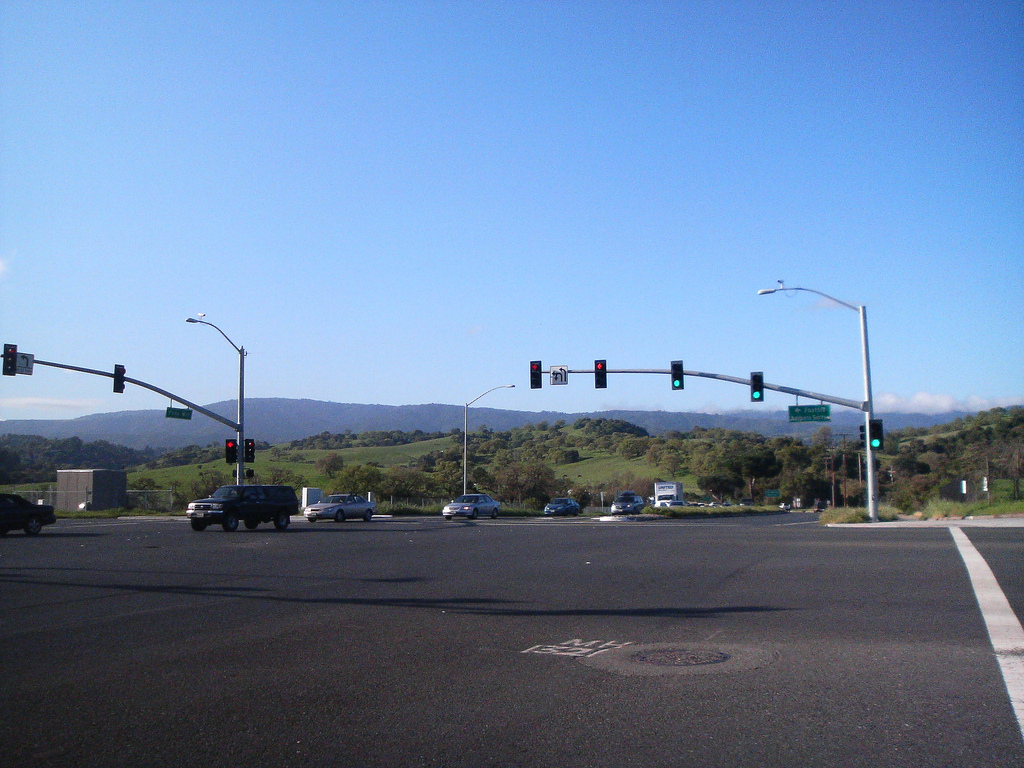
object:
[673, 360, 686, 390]
signal light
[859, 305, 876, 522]
post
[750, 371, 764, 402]
signal light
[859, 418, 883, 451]
signal light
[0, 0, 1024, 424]
sky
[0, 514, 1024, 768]
road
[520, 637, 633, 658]
marking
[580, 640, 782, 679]
manhole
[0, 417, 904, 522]
hills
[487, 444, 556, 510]
trees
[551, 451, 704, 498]
grass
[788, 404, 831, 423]
street sign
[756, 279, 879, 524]
pole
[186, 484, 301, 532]
car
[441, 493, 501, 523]
car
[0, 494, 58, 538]
car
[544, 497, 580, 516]
car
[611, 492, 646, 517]
car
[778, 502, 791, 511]
car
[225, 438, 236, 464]
traffic signal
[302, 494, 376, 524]
car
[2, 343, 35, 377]
traffic light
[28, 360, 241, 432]
pole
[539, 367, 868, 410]
pole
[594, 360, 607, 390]
traffic light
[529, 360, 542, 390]
traffic light